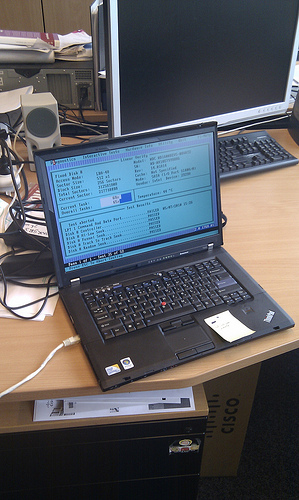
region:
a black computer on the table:
[29, 240, 227, 393]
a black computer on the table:
[35, 189, 290, 373]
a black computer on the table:
[29, 129, 242, 320]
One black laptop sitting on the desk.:
[30, 119, 295, 395]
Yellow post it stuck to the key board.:
[201, 307, 259, 348]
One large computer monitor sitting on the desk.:
[88, 1, 298, 134]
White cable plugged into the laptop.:
[2, 331, 94, 396]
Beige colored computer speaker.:
[17, 86, 66, 172]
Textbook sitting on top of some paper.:
[0, 21, 66, 53]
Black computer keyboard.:
[217, 131, 297, 174]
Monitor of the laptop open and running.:
[32, 127, 222, 275]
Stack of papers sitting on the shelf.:
[18, 385, 223, 424]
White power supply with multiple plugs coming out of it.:
[0, 114, 24, 198]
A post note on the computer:
[189, 302, 260, 352]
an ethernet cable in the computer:
[21, 321, 104, 379]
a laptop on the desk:
[20, 114, 298, 360]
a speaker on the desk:
[18, 75, 75, 173]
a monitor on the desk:
[75, 4, 297, 106]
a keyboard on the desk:
[213, 113, 298, 192]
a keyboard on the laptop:
[77, 271, 257, 321]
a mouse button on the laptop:
[154, 296, 170, 307]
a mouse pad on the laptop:
[143, 311, 211, 359]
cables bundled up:
[7, 185, 64, 337]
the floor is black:
[258, 427, 288, 479]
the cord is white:
[19, 357, 58, 380]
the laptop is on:
[63, 215, 217, 254]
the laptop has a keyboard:
[82, 275, 242, 331]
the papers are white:
[52, 394, 177, 414]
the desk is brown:
[244, 220, 294, 258]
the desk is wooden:
[257, 220, 289, 266]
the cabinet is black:
[19, 438, 197, 498]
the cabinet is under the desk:
[11, 450, 215, 497]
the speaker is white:
[18, 90, 62, 138]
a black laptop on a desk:
[37, 136, 245, 436]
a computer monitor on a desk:
[80, 19, 293, 297]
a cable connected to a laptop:
[0, 328, 84, 407]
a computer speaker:
[21, 87, 73, 175]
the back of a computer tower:
[0, 58, 90, 107]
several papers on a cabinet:
[4, 380, 203, 437]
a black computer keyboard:
[203, 120, 287, 193]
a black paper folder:
[86, 4, 105, 110]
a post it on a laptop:
[205, 284, 256, 348]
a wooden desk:
[192, 203, 291, 326]